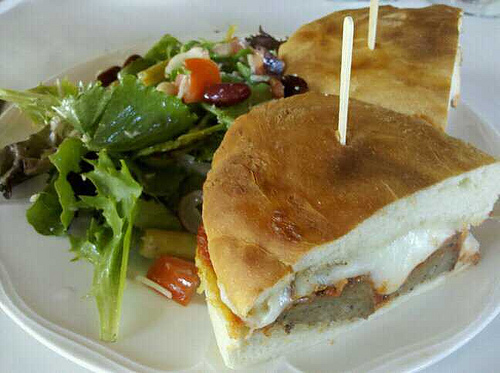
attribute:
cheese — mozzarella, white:
[322, 218, 423, 266]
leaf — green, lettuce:
[18, 98, 170, 223]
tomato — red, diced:
[122, 237, 209, 302]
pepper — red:
[163, 50, 254, 96]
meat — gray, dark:
[301, 269, 433, 314]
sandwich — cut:
[184, 53, 499, 362]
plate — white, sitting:
[6, 11, 499, 369]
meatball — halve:
[240, 274, 413, 345]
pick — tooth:
[329, 18, 366, 155]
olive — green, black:
[254, 63, 325, 101]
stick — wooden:
[319, 13, 377, 164]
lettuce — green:
[78, 84, 180, 200]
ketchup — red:
[335, 272, 400, 345]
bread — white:
[268, 79, 461, 254]